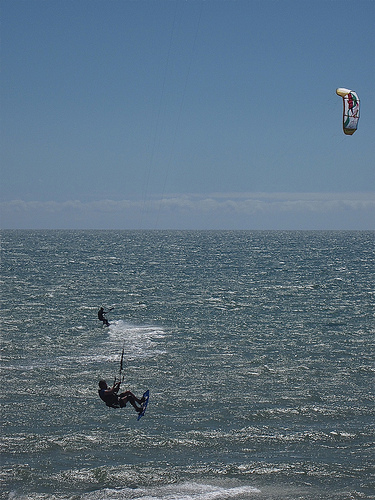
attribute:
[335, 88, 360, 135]
kite — large, colored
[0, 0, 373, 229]
sky — blue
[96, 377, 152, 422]
man — surfing, boarding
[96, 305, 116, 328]
man — surfing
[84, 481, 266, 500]
wave — small, white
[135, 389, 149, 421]
board — blue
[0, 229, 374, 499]
water — blue, wavy, calm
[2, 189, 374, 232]
clouds — gray, white